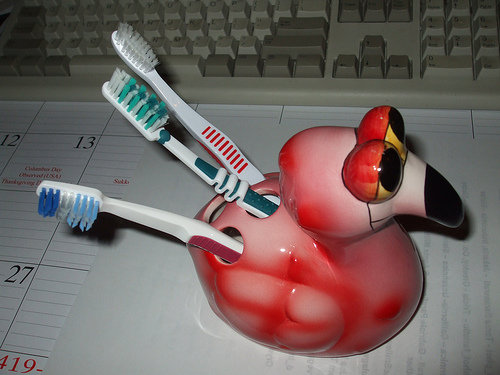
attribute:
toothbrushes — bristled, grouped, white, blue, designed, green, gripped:
[32, 21, 279, 267]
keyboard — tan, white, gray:
[4, 4, 499, 109]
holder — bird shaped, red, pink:
[193, 102, 469, 363]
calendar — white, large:
[1, 101, 499, 375]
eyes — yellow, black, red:
[339, 102, 411, 205]